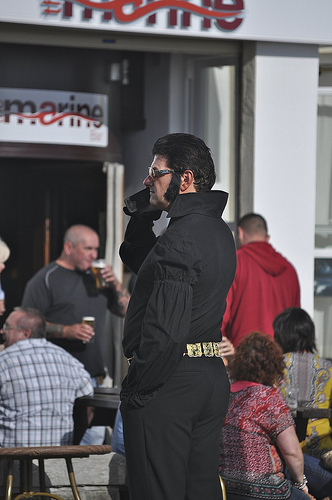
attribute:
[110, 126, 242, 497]
man — elvis impersonator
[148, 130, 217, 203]
hair — @ least partly fake, elvis hair, styled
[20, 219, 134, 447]
man — bald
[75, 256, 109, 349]
beers — twp\o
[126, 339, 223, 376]
belt — gold, black, gold plated, goldtone, golden, fancy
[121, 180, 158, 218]
cellphone — black, big, huge, older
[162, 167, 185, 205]
sideburn — black, likely faux, long, shoe polish, not real, exaggerated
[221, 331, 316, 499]
woman — sitting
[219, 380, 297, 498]
shirt — red, patterned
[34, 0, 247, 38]
sign — red, white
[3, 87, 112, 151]
sign — smaller, white, red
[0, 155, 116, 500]
doorway — smaller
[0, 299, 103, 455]
man — balding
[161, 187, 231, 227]
collar — high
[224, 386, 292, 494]
print — mostly red, busy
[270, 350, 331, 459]
shirt — mostly yellow, patterned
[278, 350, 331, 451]
print — mostly grey, busy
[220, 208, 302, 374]
man — looking down, standing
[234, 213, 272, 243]
buzz cut — black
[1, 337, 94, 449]
shirt — plaid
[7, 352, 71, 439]
plaid — blue, grey, grey+blue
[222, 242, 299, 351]
hoodie — red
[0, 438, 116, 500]
furniture — wood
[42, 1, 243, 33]
printing — red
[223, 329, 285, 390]
hair — brown, curly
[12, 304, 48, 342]
hair — thinning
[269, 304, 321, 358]
hair — black, shag cut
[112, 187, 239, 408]
shirt — black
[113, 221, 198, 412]
sleeve — strangely ruffly, puffy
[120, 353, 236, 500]
pants — black, too tight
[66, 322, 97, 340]
hand — right hand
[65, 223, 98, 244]
bald spot — huge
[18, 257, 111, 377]
shirt — grey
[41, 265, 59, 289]
seam — white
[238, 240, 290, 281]
hood — droopy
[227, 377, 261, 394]
undershirt — red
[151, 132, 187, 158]
front — puffy, backcombed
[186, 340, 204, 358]
medallion — small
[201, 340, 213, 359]
medallion — small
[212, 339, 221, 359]
medallion — small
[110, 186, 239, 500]
jumpsuit — black [if it exists]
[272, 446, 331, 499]
jeans — blue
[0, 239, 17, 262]
hair — blonde, pale